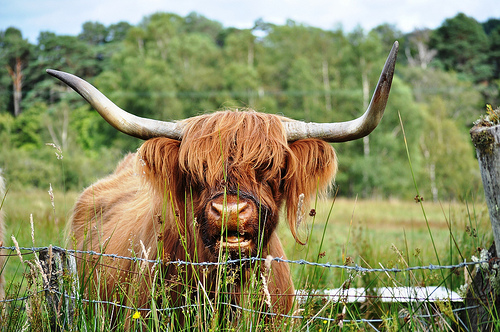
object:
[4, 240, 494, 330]
fence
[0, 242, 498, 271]
barbed wire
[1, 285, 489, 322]
barbed wire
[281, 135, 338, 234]
ear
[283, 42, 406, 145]
horn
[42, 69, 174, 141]
horn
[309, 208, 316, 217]
dot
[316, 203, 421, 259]
grass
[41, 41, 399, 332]
cow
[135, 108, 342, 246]
hair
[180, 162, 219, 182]
eyes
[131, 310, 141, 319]
flower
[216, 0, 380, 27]
skies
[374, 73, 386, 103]
dot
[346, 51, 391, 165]
tree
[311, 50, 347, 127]
tree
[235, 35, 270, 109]
tree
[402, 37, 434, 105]
tree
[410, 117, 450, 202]
tree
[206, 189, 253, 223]
nose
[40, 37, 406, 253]
table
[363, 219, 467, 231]
dirt patch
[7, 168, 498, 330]
field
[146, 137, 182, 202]
ear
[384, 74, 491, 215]
tree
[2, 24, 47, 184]
trees